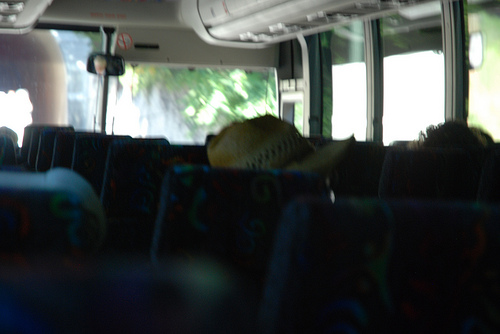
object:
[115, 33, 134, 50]
sticker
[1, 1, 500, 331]
bus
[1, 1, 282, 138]
front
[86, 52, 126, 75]
mirror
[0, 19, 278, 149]
window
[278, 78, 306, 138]
door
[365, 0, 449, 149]
windows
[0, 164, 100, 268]
seats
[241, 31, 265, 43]
lights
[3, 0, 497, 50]
ceiling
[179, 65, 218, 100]
leaves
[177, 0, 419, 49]
storage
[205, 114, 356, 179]
hat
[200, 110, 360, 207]
person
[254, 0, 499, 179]
side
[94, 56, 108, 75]
reflection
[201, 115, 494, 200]
people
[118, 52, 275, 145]
tree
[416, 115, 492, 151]
hair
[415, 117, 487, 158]
passenger